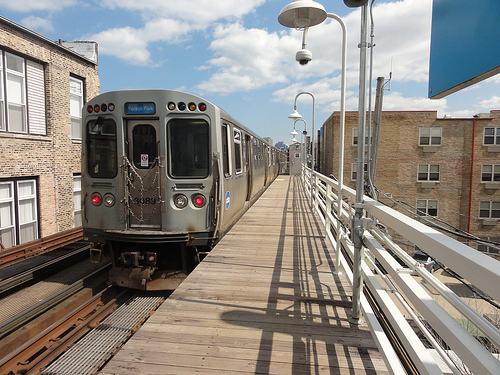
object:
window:
[418, 164, 439, 182]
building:
[314, 110, 499, 257]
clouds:
[0, 0, 499, 118]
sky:
[0, 0, 498, 146]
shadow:
[219, 310, 375, 351]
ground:
[161, 320, 362, 375]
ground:
[1, 298, 135, 375]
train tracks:
[0, 230, 155, 375]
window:
[16, 178, 39, 245]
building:
[0, 14, 100, 253]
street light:
[288, 109, 302, 142]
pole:
[312, 118, 315, 209]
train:
[76, 88, 280, 248]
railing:
[324, 182, 500, 375]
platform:
[298, 163, 349, 375]